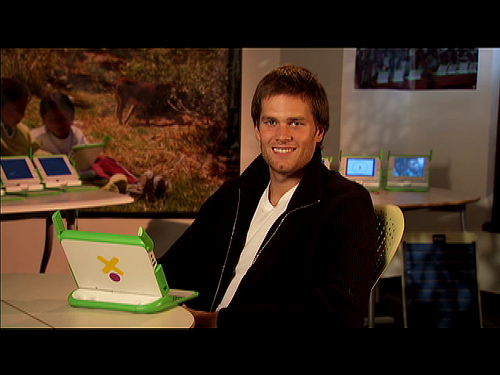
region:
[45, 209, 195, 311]
Laptop the man is using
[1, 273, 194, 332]
Table the man's laptop is sitting on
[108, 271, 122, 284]
Red dot on the back of the man's laptop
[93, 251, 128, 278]
Yellow X on the back of the man's laptop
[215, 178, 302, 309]
White shirt under the man's jacket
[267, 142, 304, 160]
Man's smiling mouth and teeth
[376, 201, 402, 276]
Back of the chair the man is sitting in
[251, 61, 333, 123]
Man's brown hair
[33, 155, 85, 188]
Second laptop on the left that is turned off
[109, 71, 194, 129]
Animal in the picture on the wall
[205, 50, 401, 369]
Tom Brady, quarterback of the Patriots.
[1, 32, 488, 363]
Tom Brady in a computer lab.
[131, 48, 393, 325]
Smiling man wearing a black jacket.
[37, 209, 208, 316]
White and green laptop computer.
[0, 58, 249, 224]
Photo on the far wall.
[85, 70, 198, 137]
Monkey in the photo.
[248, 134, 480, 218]
Table of computers behind the man.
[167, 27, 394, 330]
Man wearing a white shirt and black jacket.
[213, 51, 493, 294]
White walls behind the man.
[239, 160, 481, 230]
Round table with computers behind the man.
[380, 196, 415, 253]
edge of tan chair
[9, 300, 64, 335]
line in tan table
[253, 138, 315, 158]
beautiful smile on Tom Brady's face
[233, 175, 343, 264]
white tee shirt on body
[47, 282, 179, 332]
lime green on white tablet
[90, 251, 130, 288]
yellow cross on white cover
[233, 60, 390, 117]
short hair cut on Tom Brady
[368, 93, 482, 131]
small section of white wall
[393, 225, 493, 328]
blue book bin on ground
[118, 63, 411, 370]
gorgeous football hunk sitting at table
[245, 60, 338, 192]
Tom Brady with a bowl haircut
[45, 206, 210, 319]
a child's laptop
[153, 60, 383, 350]
football player in black jacket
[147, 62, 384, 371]
a future Hall of Fame Qback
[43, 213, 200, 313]
a plastic computer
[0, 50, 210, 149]
children superimposed in a wildlife photo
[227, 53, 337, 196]
a man with a dimple in his chin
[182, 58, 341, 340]
grown man wearing a white t-shirt in public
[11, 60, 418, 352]
man sitting in front of a desk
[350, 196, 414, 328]
a chair with holes in back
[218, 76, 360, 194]
A man with a toy computer.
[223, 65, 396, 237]
A man that does not look too bright.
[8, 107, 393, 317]
A man that looks like he is confused.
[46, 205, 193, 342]
Laptop on table.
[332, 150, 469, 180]
LCD laptops on the table.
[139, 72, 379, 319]
Man with a V neck t-shirt.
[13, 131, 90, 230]
More laptop computers on a table.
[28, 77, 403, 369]
Posing with a computer.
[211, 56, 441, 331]
Man smiling with laptop.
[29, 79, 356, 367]
Man happy with his new laptop from toys r us.